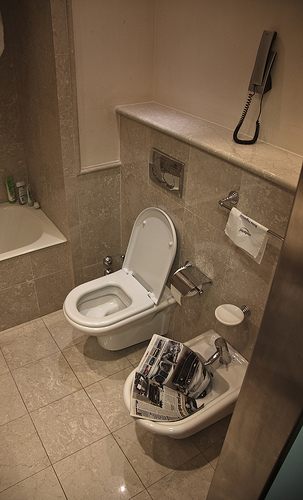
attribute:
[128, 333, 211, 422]
magazine — opened, open, black, white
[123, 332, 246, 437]
bowl — bidet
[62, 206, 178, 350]
toilet — empty, white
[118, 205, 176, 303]
lid — plastic, white, up, open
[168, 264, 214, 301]
roll of toilet paper — on dispenser, protected, covered, here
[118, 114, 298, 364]
wall — tiled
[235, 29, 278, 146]
phone — hung up, silver, corded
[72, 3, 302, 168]
wall — beige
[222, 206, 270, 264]
bag — plastic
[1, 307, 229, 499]
floor — reflective, tiled, shiny, beige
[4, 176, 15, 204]
bottle — shower gel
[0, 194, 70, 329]
bathtub — ceramic, white, tiled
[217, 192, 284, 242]
towel rack — metal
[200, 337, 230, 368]
faucet — chrome